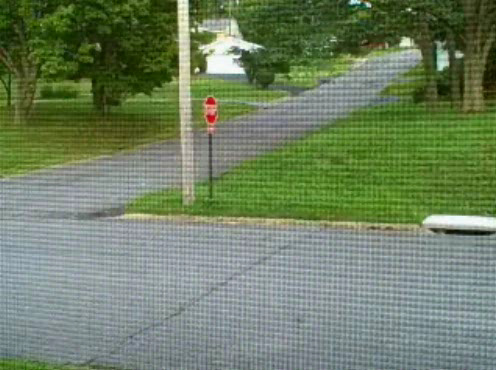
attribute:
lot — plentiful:
[179, 71, 276, 109]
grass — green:
[325, 124, 431, 197]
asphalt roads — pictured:
[1, 49, 492, 368]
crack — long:
[146, 280, 268, 328]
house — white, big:
[155, 9, 300, 81]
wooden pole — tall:
[176, 0, 197, 206]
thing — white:
[416, 206, 493, 238]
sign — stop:
[201, 94, 222, 203]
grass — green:
[308, 136, 420, 221]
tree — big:
[2, 2, 84, 127]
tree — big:
[69, 0, 176, 109]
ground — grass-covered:
[140, 44, 494, 217]